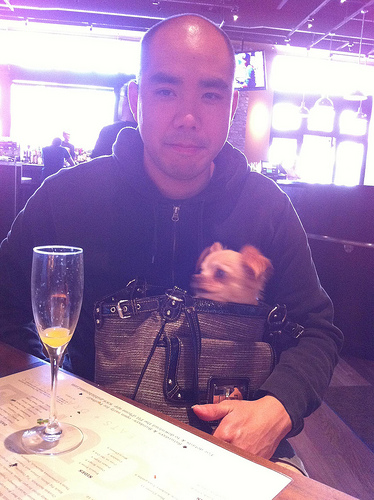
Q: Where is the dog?
A: In the purse.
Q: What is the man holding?
A: A purse.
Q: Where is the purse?
A: Man's lap.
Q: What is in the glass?
A: Juice.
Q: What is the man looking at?
A: The camera.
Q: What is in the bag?
A: Dog.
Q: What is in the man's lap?
A: Bag.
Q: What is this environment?
A: Restaurant.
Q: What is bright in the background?
A: Windows.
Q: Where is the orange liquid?
A: In the tall glass.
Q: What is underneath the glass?
A: Place mat.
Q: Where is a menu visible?
A: On the placemat.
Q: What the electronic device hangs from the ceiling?
A: Television.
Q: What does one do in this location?
A: Eat and drink.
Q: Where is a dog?
A: In a bag.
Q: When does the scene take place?
A: During the daytime.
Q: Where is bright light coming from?
A: Windows.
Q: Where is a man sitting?
A: At a table.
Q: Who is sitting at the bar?
A: A man.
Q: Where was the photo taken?
A: In a bar and restaurant.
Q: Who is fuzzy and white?
A: The dog.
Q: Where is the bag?
A: On man's lap.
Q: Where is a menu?
A: On table.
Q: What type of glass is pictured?
A: A champagne flute.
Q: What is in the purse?
A: A dog.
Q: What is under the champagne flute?
A: A menu.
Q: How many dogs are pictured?
A: One.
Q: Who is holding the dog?
A: A man.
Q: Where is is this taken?
A: A restaurant.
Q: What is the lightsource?
A: Sunlight.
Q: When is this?
A: Daytime.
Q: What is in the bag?
A: Dog.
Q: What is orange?
A: Juice.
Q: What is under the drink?
A: Menu.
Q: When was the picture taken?
A: Daytime.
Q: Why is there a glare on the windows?
A: Sunlight.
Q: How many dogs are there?
A: 1.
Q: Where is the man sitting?
A: At a bar.